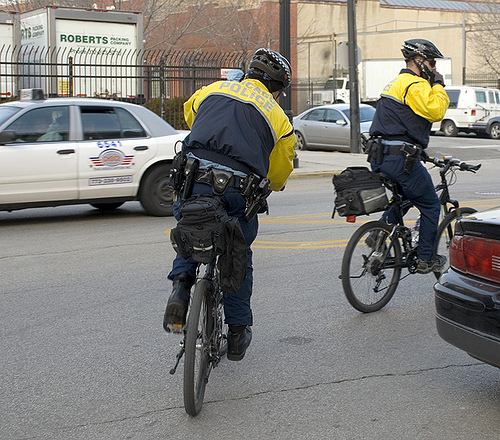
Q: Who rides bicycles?
A: Police.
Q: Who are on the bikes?
A: Police officers.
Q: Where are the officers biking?
A: On the street.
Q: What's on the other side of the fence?
A: A truck.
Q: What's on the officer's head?
A: His helmet.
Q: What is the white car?
A: A taxi.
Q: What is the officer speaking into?
A: His walkie-talkie.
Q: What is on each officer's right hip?
A: A gun.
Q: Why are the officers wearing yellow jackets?
A: To be more visible.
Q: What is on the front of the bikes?
A: Handlebars.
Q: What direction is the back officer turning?
A: Right.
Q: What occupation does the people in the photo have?
A: Police officers.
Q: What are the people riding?
A: Bicycles.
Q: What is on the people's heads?
A: Helmets.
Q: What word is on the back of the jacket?
A: Police.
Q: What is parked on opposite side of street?
A: Taxi cab.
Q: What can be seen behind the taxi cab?
A: A fence.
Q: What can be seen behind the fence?
A: Trucks.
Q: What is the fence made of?
A: Metal.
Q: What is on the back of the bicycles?
A: Bags.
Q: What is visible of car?
A: Tail light.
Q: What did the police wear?
A: Helmet.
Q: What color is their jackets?
A: Blue, yellow.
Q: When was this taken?
A: Daytime.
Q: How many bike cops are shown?
A: 2.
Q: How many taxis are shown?
A: 1.